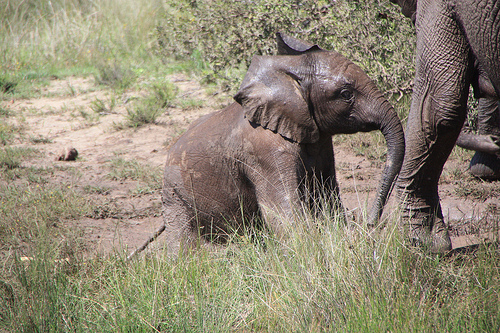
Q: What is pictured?
A: An elephant calf.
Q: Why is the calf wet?
A: From swimming.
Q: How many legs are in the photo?
A: Five.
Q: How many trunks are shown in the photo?
A: Two.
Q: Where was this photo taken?
A: A savannah.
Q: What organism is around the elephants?
A: Grass.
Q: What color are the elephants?
A: Gray.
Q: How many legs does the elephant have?
A: Four.